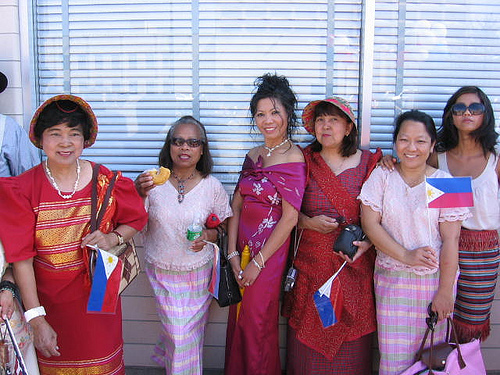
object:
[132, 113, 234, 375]
woman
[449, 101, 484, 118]
glasses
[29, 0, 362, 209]
blinds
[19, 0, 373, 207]
window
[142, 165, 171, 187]
food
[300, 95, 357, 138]
hat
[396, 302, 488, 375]
purse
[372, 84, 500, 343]
woman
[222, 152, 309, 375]
long/pink dress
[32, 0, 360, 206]
reflections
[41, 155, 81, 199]
white necklace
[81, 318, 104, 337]
bright red/dress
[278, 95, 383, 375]
woman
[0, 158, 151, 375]
dress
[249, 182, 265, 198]
design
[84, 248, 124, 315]
flag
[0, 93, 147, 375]
lady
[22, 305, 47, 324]
bracelet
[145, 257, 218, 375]
skirt